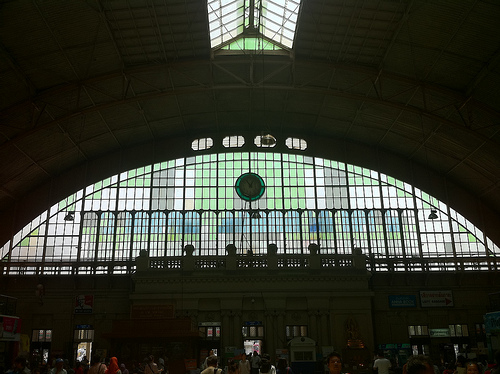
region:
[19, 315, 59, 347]
window in dome building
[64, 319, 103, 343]
window in dome building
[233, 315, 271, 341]
window in dome building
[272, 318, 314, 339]
window in dome building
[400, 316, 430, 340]
window in dome building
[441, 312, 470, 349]
window in dome building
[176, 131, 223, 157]
window in dome building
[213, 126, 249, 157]
window in dome building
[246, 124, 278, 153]
window in dome building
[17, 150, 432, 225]
the window is arched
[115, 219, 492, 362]
lights are on the window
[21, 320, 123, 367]
doorways are open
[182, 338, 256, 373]
people are walking around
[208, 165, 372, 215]
a clock is in the window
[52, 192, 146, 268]
lights are by the window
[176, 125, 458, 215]
small windows are above the arch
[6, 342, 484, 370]
Crowd of people at the station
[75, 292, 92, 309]
advertisement for chicken fast food restaraunt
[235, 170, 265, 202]
large circular clock on glass wall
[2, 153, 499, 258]
Large decorative arched window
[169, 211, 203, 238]
colorful panels of glass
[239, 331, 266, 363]
glass doorway with light pouring in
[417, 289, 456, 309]
advertisment sign with directional arrow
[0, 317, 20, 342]
sing for store inside station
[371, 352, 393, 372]
man in white shirt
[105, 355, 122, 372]
woman with red head covering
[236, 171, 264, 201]
Clock in the center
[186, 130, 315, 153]
Four small windows above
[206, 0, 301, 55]
Skylight in the buliding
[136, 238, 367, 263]
Six speakers are mounted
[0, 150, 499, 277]
Half circle of various colored glass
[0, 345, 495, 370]
People standing in line at ticket counters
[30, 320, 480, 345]
Ticket counter windows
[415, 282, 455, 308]
Sign on front of building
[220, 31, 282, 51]
Window glass is green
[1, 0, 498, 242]
Building has a rounded roof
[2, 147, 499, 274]
big window on the top of wall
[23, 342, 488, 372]
a bunch of people walking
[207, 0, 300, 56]
big skylight on the roof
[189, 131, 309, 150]
four skylight on front wall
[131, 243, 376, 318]
small white balcony in front